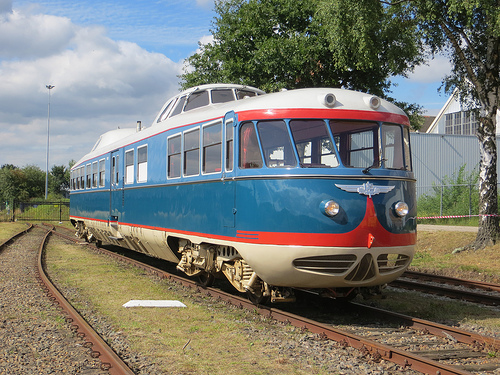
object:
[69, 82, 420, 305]
train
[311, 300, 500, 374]
track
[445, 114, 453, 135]
windows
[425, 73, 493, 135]
house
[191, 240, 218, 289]
wheels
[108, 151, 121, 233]
door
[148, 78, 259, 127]
roof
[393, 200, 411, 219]
headlights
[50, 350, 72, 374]
rocks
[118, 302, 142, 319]
grass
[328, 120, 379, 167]
windshield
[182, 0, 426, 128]
tree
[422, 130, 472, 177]
fence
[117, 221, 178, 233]
stripe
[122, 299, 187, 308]
object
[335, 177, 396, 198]
emblem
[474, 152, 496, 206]
tree bark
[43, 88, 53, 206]
pole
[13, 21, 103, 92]
clouds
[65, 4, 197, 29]
sky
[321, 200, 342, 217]
headlights